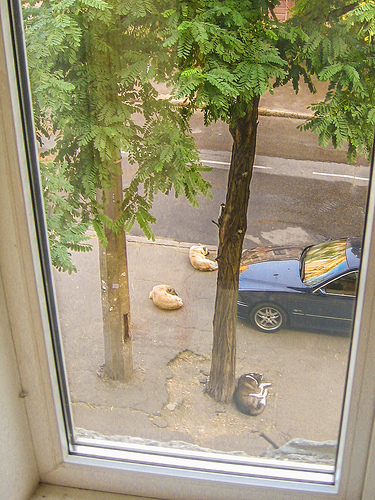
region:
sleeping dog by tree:
[231, 371, 271, 416]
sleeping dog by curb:
[184, 242, 217, 272]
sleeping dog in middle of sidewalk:
[148, 282, 183, 310]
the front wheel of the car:
[248, 304, 283, 330]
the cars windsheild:
[307, 243, 344, 274]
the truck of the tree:
[195, 151, 255, 402]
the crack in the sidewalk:
[159, 341, 235, 436]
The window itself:
[2, 9, 368, 485]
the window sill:
[30, 471, 155, 496]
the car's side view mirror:
[315, 287, 325, 296]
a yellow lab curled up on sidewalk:
[148, 283, 184, 310]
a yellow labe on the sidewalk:
[189, 243, 217, 273]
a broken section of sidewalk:
[155, 349, 262, 450]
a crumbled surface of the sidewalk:
[154, 345, 261, 455]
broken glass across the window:
[69, 414, 335, 467]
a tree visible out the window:
[20, 0, 374, 402]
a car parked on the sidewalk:
[228, 236, 368, 332]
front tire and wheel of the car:
[247, 301, 286, 334]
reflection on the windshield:
[303, 236, 348, 277]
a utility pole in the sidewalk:
[84, 0, 134, 380]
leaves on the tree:
[106, 122, 129, 142]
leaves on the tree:
[162, 152, 183, 174]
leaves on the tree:
[84, 134, 101, 162]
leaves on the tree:
[209, 79, 230, 96]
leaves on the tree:
[329, 120, 345, 148]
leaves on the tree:
[240, 65, 263, 79]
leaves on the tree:
[40, 78, 69, 93]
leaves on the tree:
[134, 50, 175, 80]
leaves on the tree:
[72, 126, 89, 141]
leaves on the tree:
[176, 33, 205, 55]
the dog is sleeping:
[226, 367, 286, 436]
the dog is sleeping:
[145, 270, 198, 331]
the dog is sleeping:
[181, 236, 224, 289]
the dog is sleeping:
[180, 250, 209, 275]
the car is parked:
[223, 209, 373, 325]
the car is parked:
[242, 244, 365, 372]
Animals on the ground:
[145, 219, 216, 324]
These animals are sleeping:
[144, 232, 292, 423]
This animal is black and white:
[227, 365, 279, 421]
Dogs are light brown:
[149, 224, 226, 319]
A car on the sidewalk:
[232, 223, 370, 356]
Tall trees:
[22, 3, 348, 406]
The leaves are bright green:
[21, 3, 359, 273]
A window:
[2, 1, 367, 498]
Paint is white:
[6, 216, 360, 498]